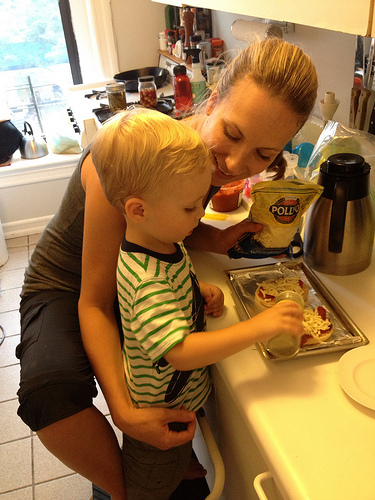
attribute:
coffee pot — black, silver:
[304, 145, 362, 280]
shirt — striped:
[109, 231, 214, 427]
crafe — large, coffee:
[298, 147, 361, 274]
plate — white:
[332, 339, 362, 418]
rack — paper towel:
[221, 16, 290, 45]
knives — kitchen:
[348, 34, 362, 79]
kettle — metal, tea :
[11, 115, 51, 160]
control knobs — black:
[60, 98, 83, 142]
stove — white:
[3, 99, 103, 163]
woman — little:
[25, 40, 325, 423]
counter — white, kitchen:
[219, 227, 362, 415]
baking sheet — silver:
[216, 254, 357, 358]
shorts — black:
[16, 276, 245, 449]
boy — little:
[96, 98, 314, 498]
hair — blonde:
[71, 96, 212, 191]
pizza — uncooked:
[249, 273, 319, 320]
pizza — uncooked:
[281, 303, 338, 350]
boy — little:
[91, 101, 297, 494]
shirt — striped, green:
[115, 235, 216, 423]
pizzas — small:
[258, 276, 329, 333]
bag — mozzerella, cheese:
[252, 175, 297, 255]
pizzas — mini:
[254, 272, 330, 340]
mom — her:
[207, 45, 294, 187]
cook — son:
[242, 266, 346, 351]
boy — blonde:
[79, 96, 254, 498]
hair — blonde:
[32, 37, 328, 481]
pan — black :
[105, 53, 191, 103]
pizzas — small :
[248, 257, 321, 359]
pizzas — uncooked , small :
[256, 260, 337, 362]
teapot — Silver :
[12, 114, 49, 161]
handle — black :
[13, 103, 40, 138]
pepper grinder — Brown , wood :
[171, 9, 199, 62]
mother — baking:
[24, 39, 320, 476]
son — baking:
[74, 90, 241, 482]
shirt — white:
[87, 246, 240, 417]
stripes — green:
[132, 290, 179, 324]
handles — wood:
[345, 91, 372, 116]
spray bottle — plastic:
[186, 46, 217, 96]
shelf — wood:
[141, 9, 218, 97]